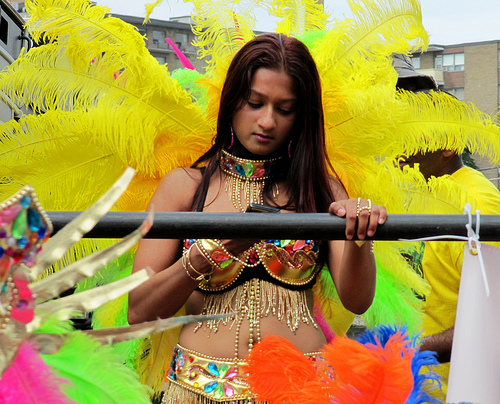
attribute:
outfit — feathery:
[7, 0, 497, 400]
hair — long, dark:
[187, 32, 350, 210]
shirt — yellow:
[397, 159, 499, 402]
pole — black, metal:
[42, 200, 494, 245]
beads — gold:
[188, 276, 330, 343]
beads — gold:
[214, 166, 301, 211]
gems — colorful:
[220, 154, 265, 181]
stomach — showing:
[179, 293, 327, 361]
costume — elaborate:
[160, 147, 325, 403]